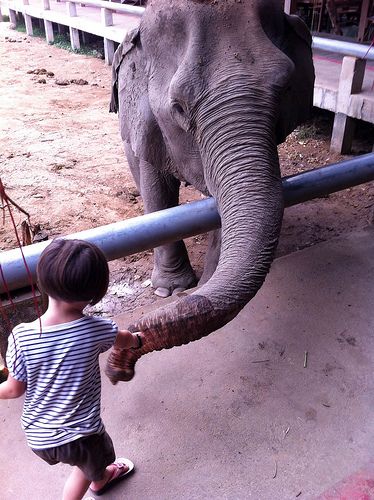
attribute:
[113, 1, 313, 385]
elephant — grey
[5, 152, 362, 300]
barrier — metal, pole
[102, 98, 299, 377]
long grey trunk — long 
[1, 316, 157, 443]
stripped shirt — striped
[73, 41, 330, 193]
grey elephant — baby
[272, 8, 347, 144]
ear of elephant — floppy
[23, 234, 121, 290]
"short hair — short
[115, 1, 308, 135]
grey elphant face — elephant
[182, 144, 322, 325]
elephant trunk — big, grey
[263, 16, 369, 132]
platform for people — wooden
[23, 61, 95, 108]
pile of dung — elephant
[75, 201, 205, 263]
metal rail — large, black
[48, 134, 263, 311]
ground is brown — dry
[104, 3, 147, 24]
rail near trunk — grey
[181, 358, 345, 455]
brown concrete — light brown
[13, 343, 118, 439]
striped shirt — blue, white